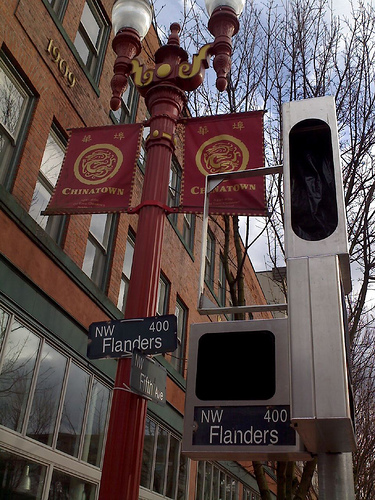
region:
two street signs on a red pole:
[87, 315, 182, 404]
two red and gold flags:
[40, 103, 273, 218]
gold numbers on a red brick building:
[41, 34, 78, 90]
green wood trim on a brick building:
[13, 195, 119, 311]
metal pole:
[314, 450, 357, 498]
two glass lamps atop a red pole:
[106, 0, 256, 37]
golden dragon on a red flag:
[79, 146, 114, 181]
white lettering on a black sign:
[96, 318, 172, 351]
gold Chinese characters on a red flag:
[195, 118, 245, 135]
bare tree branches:
[251, 1, 371, 94]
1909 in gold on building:
[38, 23, 80, 94]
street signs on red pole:
[96, 314, 169, 408]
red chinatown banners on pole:
[54, 108, 265, 225]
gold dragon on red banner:
[72, 140, 126, 190]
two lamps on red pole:
[82, 0, 248, 116]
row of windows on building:
[11, 321, 184, 497]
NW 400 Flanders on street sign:
[191, 398, 295, 444]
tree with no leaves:
[223, 126, 373, 415]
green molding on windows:
[2, 42, 71, 252]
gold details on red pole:
[113, 39, 226, 89]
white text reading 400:
[147, 320, 170, 331]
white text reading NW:
[94, 325, 120, 338]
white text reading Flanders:
[98, 335, 163, 352]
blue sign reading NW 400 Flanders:
[89, 315, 175, 354]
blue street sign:
[90, 319, 177, 355]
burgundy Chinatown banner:
[41, 125, 142, 212]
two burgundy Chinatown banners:
[39, 108, 267, 215]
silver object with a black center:
[281, 94, 348, 254]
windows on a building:
[0, 304, 109, 496]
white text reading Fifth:
[136, 371, 154, 392]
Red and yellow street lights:
[65, 0, 250, 107]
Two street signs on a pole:
[80, 289, 179, 417]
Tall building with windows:
[7, 0, 105, 478]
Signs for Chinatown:
[36, 103, 275, 220]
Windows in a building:
[2, 297, 108, 480]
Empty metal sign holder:
[193, 161, 286, 314]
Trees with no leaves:
[225, 0, 367, 106]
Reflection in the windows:
[0, 315, 99, 467]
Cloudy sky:
[226, 0, 297, 268]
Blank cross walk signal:
[184, 310, 298, 456]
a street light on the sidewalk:
[107, 0, 240, 108]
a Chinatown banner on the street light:
[38, 110, 138, 211]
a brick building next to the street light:
[0, 0, 106, 121]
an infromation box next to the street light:
[181, 315, 295, 452]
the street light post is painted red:
[122, 84, 182, 315]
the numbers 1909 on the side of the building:
[45, 34, 75, 88]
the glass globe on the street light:
[110, 0, 153, 38]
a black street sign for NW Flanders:
[87, 314, 178, 357]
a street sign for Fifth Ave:
[130, 353, 166, 403]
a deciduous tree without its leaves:
[245, 0, 374, 95]